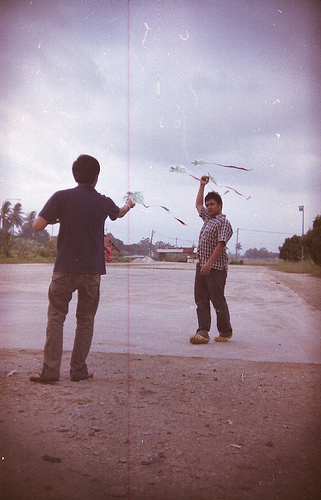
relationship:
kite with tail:
[116, 184, 150, 216] [142, 198, 188, 232]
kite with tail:
[161, 158, 195, 179] [183, 167, 255, 206]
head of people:
[69, 144, 107, 189] [28, 153, 136, 382]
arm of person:
[26, 189, 56, 239] [19, 149, 146, 388]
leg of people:
[64, 278, 104, 373] [28, 153, 136, 382]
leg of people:
[36, 268, 73, 379] [28, 153, 136, 382]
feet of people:
[22, 363, 99, 388] [28, 153, 136, 382]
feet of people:
[26, 361, 94, 386] [28, 153, 136, 382]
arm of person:
[102, 193, 129, 225] [19, 149, 146, 388]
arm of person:
[190, 184, 209, 218] [182, 188, 236, 352]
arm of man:
[205, 219, 233, 268] [189, 175, 234, 344]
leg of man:
[190, 261, 213, 329] [189, 175, 234, 344]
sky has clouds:
[0, 0, 316, 253] [41, 88, 136, 145]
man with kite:
[189, 175, 234, 344] [169, 165, 229, 198]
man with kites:
[189, 175, 234, 344] [102, 143, 268, 237]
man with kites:
[182, 189, 250, 315] [105, 152, 246, 230]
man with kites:
[189, 175, 234, 344] [105, 152, 246, 230]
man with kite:
[189, 175, 234, 344] [122, 190, 188, 227]